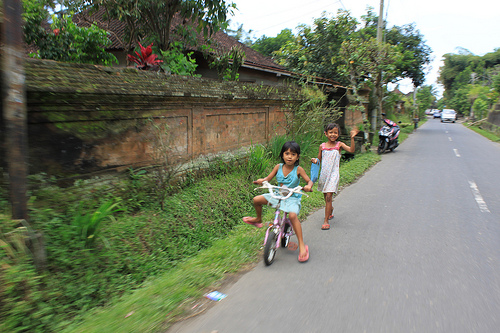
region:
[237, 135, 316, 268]
a little girl is about to ride a bike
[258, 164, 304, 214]
a blue outfit is on the girl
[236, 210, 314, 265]
flip flops on the girl are pink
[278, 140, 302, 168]
the girl has black hair and bangs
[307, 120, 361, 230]
a child is walking down the street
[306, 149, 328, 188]
the girl is carrying a blue bag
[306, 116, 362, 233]
the child is waving with her left hand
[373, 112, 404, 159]
a motorcycle is parked on the side of the road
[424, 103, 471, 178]
cars are coming up the road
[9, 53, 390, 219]
a stone fence is behind the girls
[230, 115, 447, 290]
Kids on the road.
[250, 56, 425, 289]
Kids riding their bikes.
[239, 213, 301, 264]
Tire of the bicycle.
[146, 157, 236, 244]
Grass by the wall.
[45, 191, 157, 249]
Plant in the grass.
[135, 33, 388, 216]
Wall by the road.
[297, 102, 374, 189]
Girl in a white dress.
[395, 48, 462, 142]
Cars on the road.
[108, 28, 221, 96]
Flower on the wall.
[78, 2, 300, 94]
Roof on the building.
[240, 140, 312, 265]
Girl is riding a bicycle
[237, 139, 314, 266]
Girl is riding a pink bicycle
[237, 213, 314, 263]
Girl is wearing sandals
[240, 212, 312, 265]
Girl is wearing pink sandals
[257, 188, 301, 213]
Girl is wearing a skirt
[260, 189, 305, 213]
Girl is wearing a blue skirt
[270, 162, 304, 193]
Girl is wearing a shirt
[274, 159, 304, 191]
Girl is wearing a blue shirt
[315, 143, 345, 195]
Girl is wearing a dress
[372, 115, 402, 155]
Motorcycle is on the side of the road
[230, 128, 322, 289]
dark haired girl riding bike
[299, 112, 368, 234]
girl waving at camera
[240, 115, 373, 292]
girls at side of road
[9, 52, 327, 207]
brick wall with moss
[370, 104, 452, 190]
motorcycle parked by road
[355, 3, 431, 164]
telephone pole by road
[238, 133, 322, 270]
girl wearing blue top and skirt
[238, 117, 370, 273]
girls wearing flip flops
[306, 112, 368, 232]
girl wearing white sundress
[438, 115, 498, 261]
white line on road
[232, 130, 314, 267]
a child on a bike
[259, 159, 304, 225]
she is wearing a blue dress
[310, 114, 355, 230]
this girl is walking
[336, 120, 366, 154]
her left arm is waving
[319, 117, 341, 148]
the girl is smiling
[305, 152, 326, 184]
a blue bag on her arm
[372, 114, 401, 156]
a motorcycle parked on the street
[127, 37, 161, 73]
a red flower on the wall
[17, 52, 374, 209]
a wall along the street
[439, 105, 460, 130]
a car driving down the street